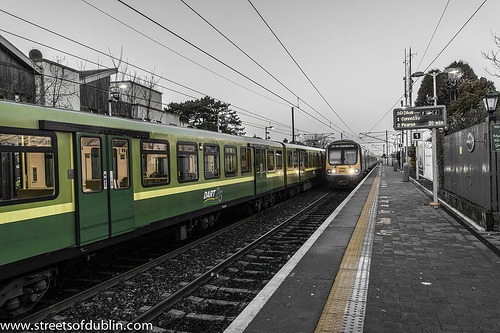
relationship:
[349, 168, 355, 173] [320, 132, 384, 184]
headlight reflecting off train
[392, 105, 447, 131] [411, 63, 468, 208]
post on post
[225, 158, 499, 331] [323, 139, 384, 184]
walkway next to train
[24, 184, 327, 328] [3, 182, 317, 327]
gravel between tracks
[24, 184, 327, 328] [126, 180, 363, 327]
gravel between tracks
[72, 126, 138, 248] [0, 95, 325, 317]
doors on side of train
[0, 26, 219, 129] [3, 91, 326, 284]
buildings behind train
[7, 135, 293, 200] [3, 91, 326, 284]
lights on train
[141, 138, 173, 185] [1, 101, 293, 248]
window of train